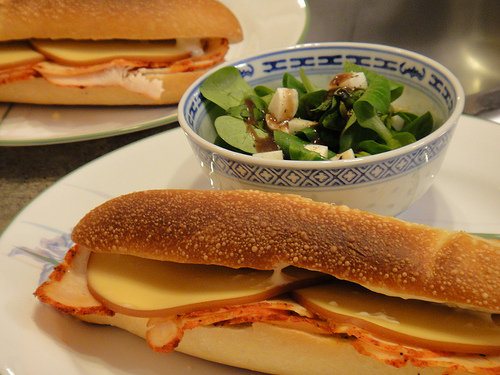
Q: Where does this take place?
A: A cafe.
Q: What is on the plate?
A: A sandwich.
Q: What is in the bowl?
A: Salad.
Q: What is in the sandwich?
A: Turkey and cheese.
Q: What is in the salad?
A: Leafy greens, cheese, and dressing.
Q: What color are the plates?
A: White.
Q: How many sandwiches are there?
A: 2 sandwiches.